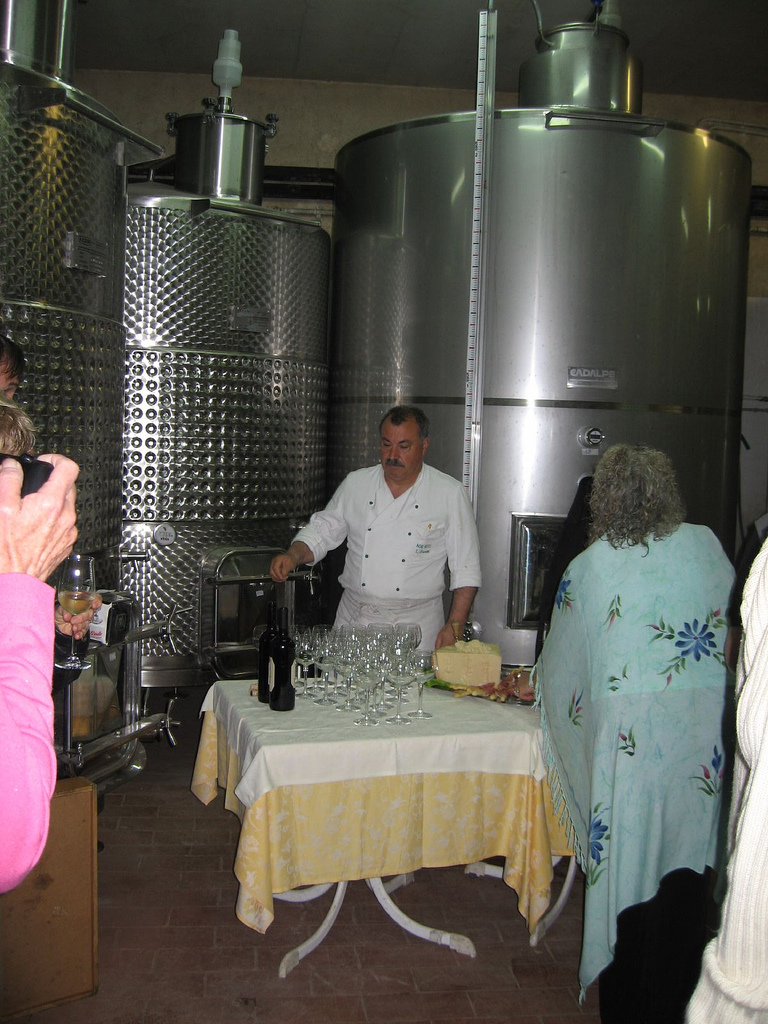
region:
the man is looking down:
[258, 367, 492, 640]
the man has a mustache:
[343, 376, 440, 506]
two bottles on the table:
[240, 568, 300, 723]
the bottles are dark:
[247, 583, 318, 722]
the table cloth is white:
[229, 658, 528, 789]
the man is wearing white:
[264, 390, 487, 632]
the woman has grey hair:
[541, 411, 724, 603]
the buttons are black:
[345, 482, 432, 593]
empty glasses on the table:
[275, 591, 443, 719]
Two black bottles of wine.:
[259, 598, 296, 714]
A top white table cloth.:
[197, 677, 548, 809]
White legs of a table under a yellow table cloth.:
[267, 875, 475, 975]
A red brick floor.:
[96, 740, 599, 1018]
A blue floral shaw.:
[528, 522, 739, 1004]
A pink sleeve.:
[1, 571, 56, 891]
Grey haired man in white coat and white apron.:
[266, 405, 481, 677]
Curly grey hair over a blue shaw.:
[590, 444, 683, 559]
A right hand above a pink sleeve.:
[2, 451, 77, 579]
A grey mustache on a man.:
[381, 458, 404, 468]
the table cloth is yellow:
[192, 709, 568, 937]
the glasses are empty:
[293, 615, 427, 732]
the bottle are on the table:
[255, 583, 303, 710]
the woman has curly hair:
[587, 445, 683, 551]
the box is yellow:
[433, 643, 503, 697]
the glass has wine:
[59, 552, 95, 668]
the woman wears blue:
[530, 524, 740, 997]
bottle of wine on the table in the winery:
[264, 598, 300, 713]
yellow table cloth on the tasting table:
[192, 727, 567, 925]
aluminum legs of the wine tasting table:
[275, 882, 479, 975]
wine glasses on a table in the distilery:
[298, 623, 438, 731]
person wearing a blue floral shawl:
[531, 443, 732, 1021]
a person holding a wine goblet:
[55, 552, 98, 672]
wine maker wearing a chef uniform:
[270, 404, 481, 627]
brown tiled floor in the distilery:
[98, 798, 230, 1020]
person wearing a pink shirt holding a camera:
[0, 445, 83, 894]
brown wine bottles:
[245, 587, 294, 681]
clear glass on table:
[327, 645, 362, 705]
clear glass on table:
[387, 633, 442, 708]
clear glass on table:
[337, 629, 368, 689]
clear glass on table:
[379, 613, 411, 675]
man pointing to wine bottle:
[263, 386, 498, 740]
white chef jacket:
[303, 461, 477, 605]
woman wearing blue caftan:
[517, 432, 733, 1005]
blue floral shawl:
[538, 519, 735, 983]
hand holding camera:
[5, 444, 81, 584]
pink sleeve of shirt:
[3, 574, 78, 919]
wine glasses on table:
[287, 599, 455, 731]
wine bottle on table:
[263, 609, 298, 711]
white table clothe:
[194, 676, 556, 795]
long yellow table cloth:
[185, 709, 583, 943]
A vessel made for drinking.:
[383, 650, 413, 727]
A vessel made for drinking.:
[350, 649, 388, 718]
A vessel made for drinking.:
[398, 619, 423, 639]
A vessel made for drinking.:
[312, 641, 338, 707]